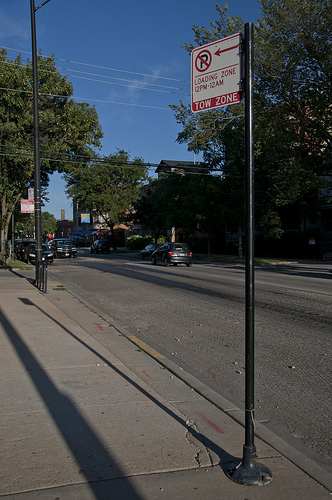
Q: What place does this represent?
A: It represents the sidewalk.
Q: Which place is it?
A: It is a sidewalk.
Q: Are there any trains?
A: No, there are no trains.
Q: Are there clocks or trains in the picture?
A: No, there are no trains or clocks.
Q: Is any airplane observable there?
A: No, there are no airplanes.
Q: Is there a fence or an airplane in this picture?
A: No, there are no airplanes or fences.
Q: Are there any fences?
A: No, there are no fences.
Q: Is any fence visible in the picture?
A: No, there are no fences.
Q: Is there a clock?
A: No, there are no clocks.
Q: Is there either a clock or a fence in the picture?
A: No, there are no clocks or fences.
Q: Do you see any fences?
A: No, there are no fences.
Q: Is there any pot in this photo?
A: No, there are no pots.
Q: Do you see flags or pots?
A: No, there are no pots or flags.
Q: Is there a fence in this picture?
A: No, there are no fences.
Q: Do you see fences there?
A: No, there are no fences.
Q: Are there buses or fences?
A: No, there are no fences or buses.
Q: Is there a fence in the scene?
A: No, there are no fences.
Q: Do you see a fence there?
A: No, there are no fences.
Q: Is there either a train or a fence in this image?
A: No, there are no fences or trains.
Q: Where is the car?
A: The car is on the road.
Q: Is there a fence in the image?
A: No, there are no fences.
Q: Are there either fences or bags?
A: No, there are no fences or bags.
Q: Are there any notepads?
A: No, there are no notepads.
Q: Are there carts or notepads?
A: No, there are no notepads or carts.